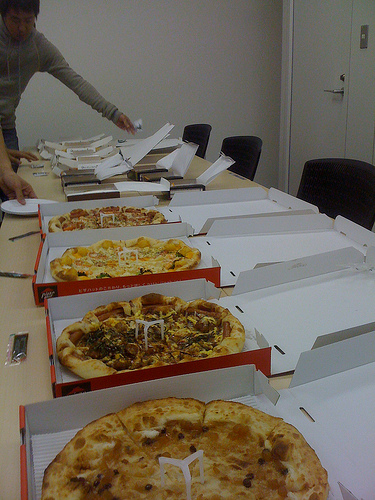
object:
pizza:
[47, 206, 169, 231]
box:
[38, 188, 318, 239]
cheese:
[137, 428, 160, 439]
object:
[157, 449, 206, 498]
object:
[119, 245, 138, 263]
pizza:
[56, 290, 244, 379]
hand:
[5, 145, 35, 167]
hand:
[111, 112, 136, 136]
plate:
[0, 198, 53, 217]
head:
[0, 0, 41, 42]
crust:
[206, 398, 279, 433]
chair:
[296, 156, 375, 232]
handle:
[322, 85, 346, 97]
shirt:
[0, 32, 123, 143]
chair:
[183, 122, 213, 157]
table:
[1, 145, 373, 499]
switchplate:
[358, 25, 368, 50]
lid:
[277, 329, 375, 499]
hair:
[0, 1, 40, 20]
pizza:
[50, 236, 202, 282]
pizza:
[117, 396, 207, 482]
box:
[42, 245, 375, 398]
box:
[18, 328, 375, 499]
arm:
[39, 31, 119, 125]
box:
[30, 213, 375, 308]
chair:
[219, 136, 262, 183]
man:
[0, 0, 139, 222]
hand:
[3, 176, 39, 206]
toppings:
[133, 316, 165, 348]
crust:
[57, 347, 112, 379]